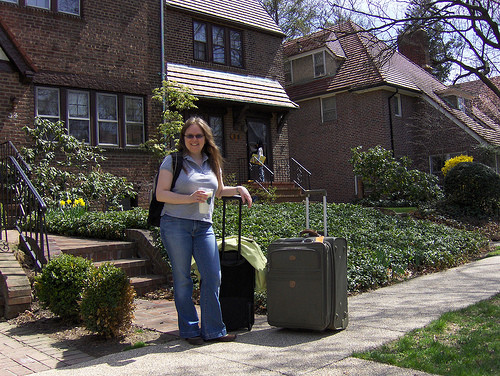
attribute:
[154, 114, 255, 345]
girl — standing, ready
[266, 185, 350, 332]
suitcase — grey, rolling, large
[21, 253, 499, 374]
sidewalk — cement, grey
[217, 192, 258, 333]
suitcase — black, rolling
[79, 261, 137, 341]
bush — small, green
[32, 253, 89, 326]
bush — small, green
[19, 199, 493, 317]
ground cover — ivy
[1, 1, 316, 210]
house — big, brown, red, brick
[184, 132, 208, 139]
sunglasses — black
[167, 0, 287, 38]
roof — brown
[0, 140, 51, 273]
rail — black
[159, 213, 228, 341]
jeans — blue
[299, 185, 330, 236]
handle — extended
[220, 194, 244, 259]
handle — extended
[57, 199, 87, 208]
flowers — yellow